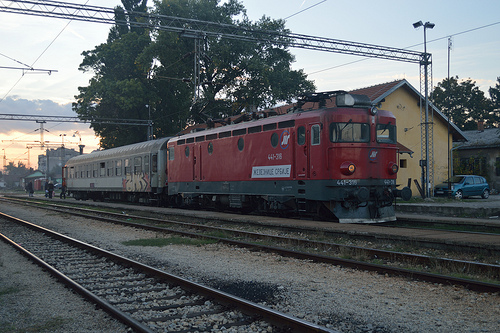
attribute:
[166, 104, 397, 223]
train engine — large, red, black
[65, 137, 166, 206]
passenger car — grey, gray, silver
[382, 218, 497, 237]
tracks — metal, empty, iron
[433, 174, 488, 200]
car — small, parked, blue, green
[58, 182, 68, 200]
person — walking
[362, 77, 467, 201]
building — yellow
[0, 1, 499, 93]
sky — blue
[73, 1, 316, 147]
tree — tall